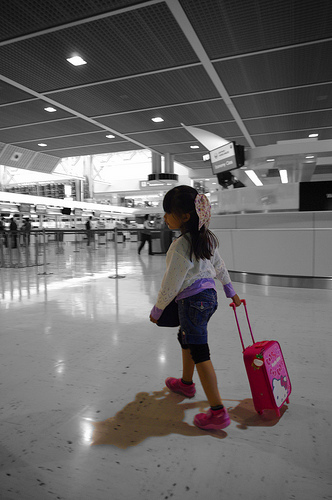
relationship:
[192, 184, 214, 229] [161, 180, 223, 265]
bow in hair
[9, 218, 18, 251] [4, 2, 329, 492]
person standing in airport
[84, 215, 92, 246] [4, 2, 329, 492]
person standing in airport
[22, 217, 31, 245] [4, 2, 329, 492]
person standing in airport